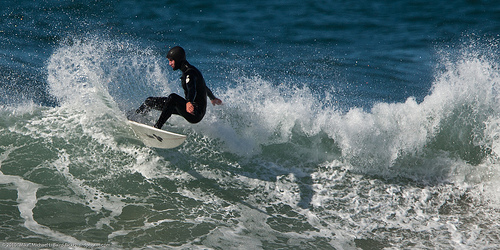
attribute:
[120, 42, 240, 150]
person — wearing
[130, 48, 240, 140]
wet suit — black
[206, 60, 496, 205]
wave — splashing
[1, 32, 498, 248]
wave — splashing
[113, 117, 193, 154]
surfboard — white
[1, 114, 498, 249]
water — foamy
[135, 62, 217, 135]
wetsuit — black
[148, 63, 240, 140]
wet suit — black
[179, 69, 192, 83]
costume — black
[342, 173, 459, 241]
water — foamy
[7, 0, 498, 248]
water — ocean, splashy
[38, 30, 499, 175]
wave — breaking, splashing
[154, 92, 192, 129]
leg — bent 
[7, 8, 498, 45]
blue — deep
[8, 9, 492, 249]
ocean — blue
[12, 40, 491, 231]
wave — big